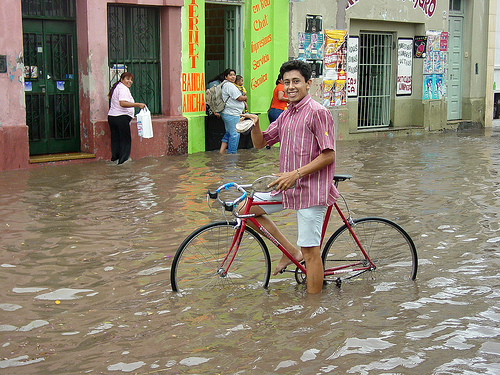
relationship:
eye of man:
[291, 78, 301, 85] [265, 59, 339, 292]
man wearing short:
[228, 51, 334, 296] [233, 179, 345, 259]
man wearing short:
[228, 51, 334, 296] [263, 173, 343, 254]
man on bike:
[228, 51, 334, 296] [176, 178, 419, 318]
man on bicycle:
[228, 51, 334, 305] [168, 168, 420, 295]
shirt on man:
[263, 96, 346, 208] [239, 62, 344, 298]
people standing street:
[204, 70, 290, 148] [42, 175, 104, 323]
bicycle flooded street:
[171, 168, 430, 301] [70, 282, 155, 361]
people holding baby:
[212, 68, 248, 156] [235, 68, 254, 104]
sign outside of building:
[178, 0, 212, 150] [53, 0, 383, 207]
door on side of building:
[13, 0, 105, 158] [0, 0, 220, 188]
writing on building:
[179, 0, 216, 98] [78, 5, 415, 194]